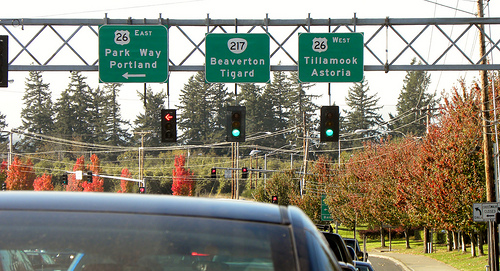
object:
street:
[0, 190, 499, 270]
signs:
[99, 25, 170, 83]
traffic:
[0, 189, 372, 269]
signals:
[319, 105, 341, 142]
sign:
[206, 33, 271, 83]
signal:
[225, 104, 246, 142]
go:
[232, 128, 240, 136]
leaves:
[352, 137, 472, 196]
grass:
[450, 257, 477, 265]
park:
[327, 152, 443, 198]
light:
[161, 110, 177, 143]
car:
[0, 190, 344, 270]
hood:
[0, 189, 292, 225]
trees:
[348, 113, 481, 215]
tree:
[398, 134, 436, 243]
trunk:
[423, 226, 431, 253]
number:
[229, 41, 245, 51]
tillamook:
[303, 55, 360, 65]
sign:
[299, 32, 364, 82]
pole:
[0, 17, 499, 25]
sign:
[470, 201, 498, 221]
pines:
[13, 70, 431, 208]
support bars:
[25, 24, 100, 66]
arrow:
[163, 113, 175, 121]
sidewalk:
[367, 252, 456, 271]